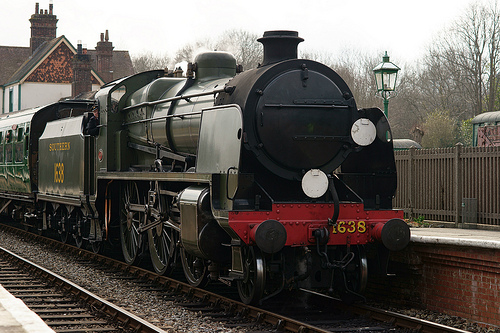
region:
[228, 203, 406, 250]
a red bumper on an engine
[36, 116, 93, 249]
the car for fuel for the engine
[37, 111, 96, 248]
the coal car of the train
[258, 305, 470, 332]
the tracks ahead of the train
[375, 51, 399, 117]
an attractive light fixture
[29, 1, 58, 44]
a chimney on the building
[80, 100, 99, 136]
the engineer of the train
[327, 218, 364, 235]
numbers on the engine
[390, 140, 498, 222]
a fence with tight pickets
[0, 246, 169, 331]
a train track beside the train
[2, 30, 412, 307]
old steam locomotive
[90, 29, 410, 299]
steam train engine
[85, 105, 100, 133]
train conductor hanging head out of engine window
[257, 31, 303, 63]
black smoke stack on train engine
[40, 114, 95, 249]
green coal car behind the engine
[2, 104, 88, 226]
green passenger car behind the coal car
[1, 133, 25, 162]
windows on passenger car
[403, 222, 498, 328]
train platform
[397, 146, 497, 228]
fence behind train platform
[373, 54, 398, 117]
green lamppost on train platform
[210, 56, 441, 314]
front of a train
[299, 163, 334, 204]
light of a train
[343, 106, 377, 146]
light of a train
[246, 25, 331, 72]
pipe of a train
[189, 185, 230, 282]
wheel of a train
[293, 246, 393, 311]
wheel of a train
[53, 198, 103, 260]
wheel of a train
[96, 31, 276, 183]
engine of a train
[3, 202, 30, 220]
wheel of a train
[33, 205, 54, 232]
wheel of a train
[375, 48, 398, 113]
Street light at station house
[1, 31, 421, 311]
Black train at train station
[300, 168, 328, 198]
Round circle on front of plane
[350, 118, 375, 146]
Round circle on front of plane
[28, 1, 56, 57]
Chimney on roof of building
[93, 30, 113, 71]
Chimney on roof of building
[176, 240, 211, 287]
wheel on train tracks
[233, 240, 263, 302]
wheel on train tracks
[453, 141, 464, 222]
fence post is brown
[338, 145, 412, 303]
fence post is brown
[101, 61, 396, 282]
the front of a black train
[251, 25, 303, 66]
the chimney part of a train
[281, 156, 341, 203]
the front light of a train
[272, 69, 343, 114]
the front window of a train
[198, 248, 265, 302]
the wheels of a train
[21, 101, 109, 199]
the second car of a train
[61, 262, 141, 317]
a bunch of small gravel and rock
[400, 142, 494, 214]
a short brown picket fence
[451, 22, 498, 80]
a barren tree branch without leaves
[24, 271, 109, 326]
a set of metal train tracks